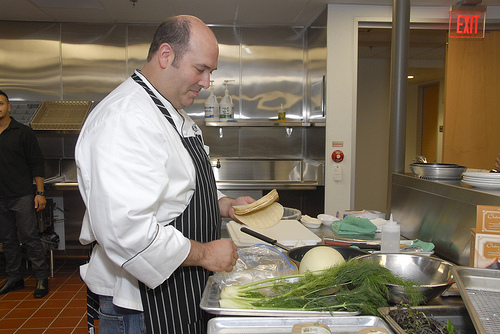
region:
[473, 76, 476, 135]
This door has a very light wood color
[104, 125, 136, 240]
This man's shirt has a very bright white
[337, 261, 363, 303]
This green looks to be something like dill weed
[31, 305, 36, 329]
The red tile in this kitchen is very clean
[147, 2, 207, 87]
This man's head is very, very bald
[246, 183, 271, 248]
This man is holding several tortillas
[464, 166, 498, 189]
There are a stack of white plates on the line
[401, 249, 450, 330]
This steel bowl is very bright in color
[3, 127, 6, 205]
This man is wearing a dark black shirt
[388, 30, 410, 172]
There is a pole that is visible in the background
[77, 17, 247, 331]
chef wearing white shirt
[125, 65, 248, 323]
black and white apron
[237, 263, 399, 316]
green vegetables in a pan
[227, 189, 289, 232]
round tan pita bread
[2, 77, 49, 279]
man standing in background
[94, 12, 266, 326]
man who is balding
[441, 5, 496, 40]
red transparent exit sign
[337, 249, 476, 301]
round metal bowl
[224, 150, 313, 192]
metal sink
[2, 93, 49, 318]
man wearing black shirt and black pants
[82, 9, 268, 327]
man working in kitchen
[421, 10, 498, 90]
red exit sign over door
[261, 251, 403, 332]
green and white vegetable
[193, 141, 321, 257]
bread in mans hand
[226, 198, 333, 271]
black knife on white cutting board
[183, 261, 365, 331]
vegetables in metal pan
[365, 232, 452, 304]
empty metal bowl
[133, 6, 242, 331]
man wearing black and white striped apron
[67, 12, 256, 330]
man wearing white chef's shirt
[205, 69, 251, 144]
chemicals on counter in kitchen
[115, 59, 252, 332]
black and white chefs apron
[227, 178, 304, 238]
pita bread in chefs hand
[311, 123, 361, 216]
red fire alarm box on wall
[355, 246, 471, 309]
large metal mising bowl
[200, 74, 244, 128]
white bottles with pump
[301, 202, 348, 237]
small round white glass dishes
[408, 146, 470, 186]
gray plates sitting on shelf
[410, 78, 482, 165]
wooden door down hall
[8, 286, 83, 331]
red tile floor in kitchen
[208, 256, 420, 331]
fresh herbs laing in tray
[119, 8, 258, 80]
Male pattern baldness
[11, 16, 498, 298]
Chef in a commercial kitchen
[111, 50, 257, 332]
Black and white striped apron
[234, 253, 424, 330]
Fresh greens on the tray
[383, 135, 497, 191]
Dishes on the counter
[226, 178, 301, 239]
Taco shells in left hand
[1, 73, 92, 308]
Man watching from behind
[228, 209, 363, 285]
Frying pan within reach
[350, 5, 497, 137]
Doorway with exit sign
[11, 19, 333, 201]
Lots of reflections in the chrome fixtures